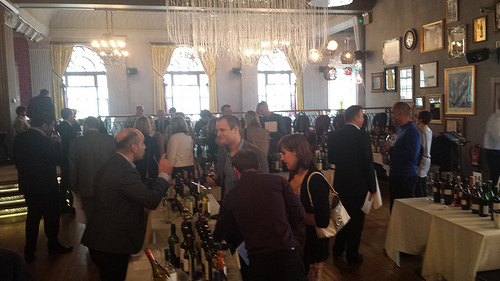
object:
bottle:
[480, 182, 495, 218]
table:
[389, 197, 500, 281]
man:
[80, 126, 175, 281]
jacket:
[165, 132, 196, 168]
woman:
[274, 133, 336, 281]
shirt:
[387, 120, 424, 177]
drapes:
[277, 42, 306, 114]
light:
[325, 40, 340, 53]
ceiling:
[0, 0, 379, 15]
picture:
[416, 21, 447, 55]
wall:
[351, 0, 500, 173]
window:
[162, 44, 214, 109]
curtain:
[49, 41, 75, 122]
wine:
[431, 171, 444, 204]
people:
[328, 105, 380, 267]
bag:
[304, 170, 351, 239]